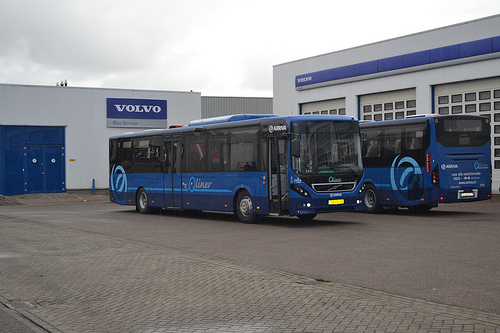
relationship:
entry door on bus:
[267, 132, 289, 215] [112, 110, 373, 226]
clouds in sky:
[68, 4, 243, 84] [1, 1, 498, 97]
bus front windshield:
[103, 113, 372, 223] [284, 109, 369, 177]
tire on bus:
[227, 192, 260, 222] [105, 113, 353, 225]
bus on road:
[354, 115, 495, 212] [291, 229, 482, 299]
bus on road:
[103, 113, 372, 223] [2, 189, 498, 327]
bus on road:
[354, 115, 498, 215] [28, 232, 497, 316]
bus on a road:
[112, 110, 373, 226] [2, 189, 498, 327]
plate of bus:
[458, 188, 475, 198] [317, 113, 494, 214]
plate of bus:
[327, 198, 345, 205] [112, 110, 373, 226]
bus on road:
[112, 110, 373, 226] [3, 218, 493, 326]